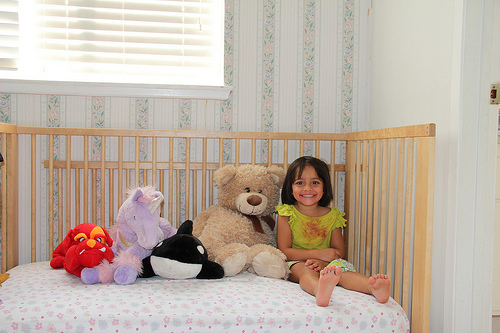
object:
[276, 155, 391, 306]
girl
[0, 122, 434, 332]
bed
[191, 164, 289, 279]
teddy bear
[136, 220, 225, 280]
whale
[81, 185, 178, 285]
unicorn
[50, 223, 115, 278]
bulldog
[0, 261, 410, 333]
mattress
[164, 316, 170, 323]
flower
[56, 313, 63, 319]
flower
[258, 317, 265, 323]
flower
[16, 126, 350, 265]
headboard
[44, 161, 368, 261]
footboard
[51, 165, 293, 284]
stuffed animals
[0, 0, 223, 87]
window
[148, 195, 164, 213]
horn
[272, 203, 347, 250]
blouse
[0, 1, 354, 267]
wallpaper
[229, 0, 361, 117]
wall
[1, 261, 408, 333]
sheet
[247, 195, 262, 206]
brown nose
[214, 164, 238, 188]
ear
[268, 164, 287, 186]
ear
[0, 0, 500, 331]
room